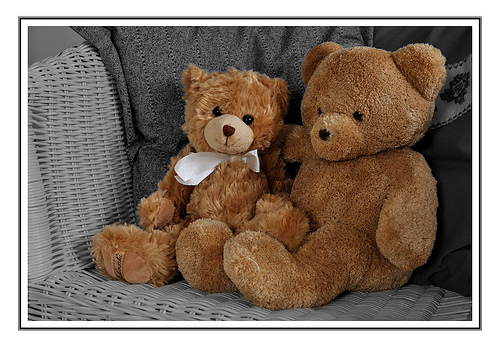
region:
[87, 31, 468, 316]
teddy bears in a chair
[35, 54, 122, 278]
wicker side of a chair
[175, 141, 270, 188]
white bow on a bear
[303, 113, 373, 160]
nose of a teddy bear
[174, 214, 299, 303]
front paws of a large bear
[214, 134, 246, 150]
mouth on a teddy bear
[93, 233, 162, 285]
front paws of a little bear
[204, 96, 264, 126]
eyes of a little teddy bear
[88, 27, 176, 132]
blanket on a chair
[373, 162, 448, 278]
arm of a teddy bear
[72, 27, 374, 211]
a grey blanket in a chair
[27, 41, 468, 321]
a white wicker chair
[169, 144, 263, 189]
a bow around a stuffed bear's neck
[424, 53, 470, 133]
white decorative trim on a blanket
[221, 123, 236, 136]
a brown nose on a stuffed bear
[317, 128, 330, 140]
a black nose on a stuffed bear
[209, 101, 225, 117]
a black eye on a stuffed bea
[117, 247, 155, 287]
a cloth pad on the bottom of a stuffed bear's paw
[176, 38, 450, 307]
a comfy stuffed bear in a wicker chair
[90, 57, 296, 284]
a shaggy stuffed bear in a wicker chair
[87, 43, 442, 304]
Two brown teddy bears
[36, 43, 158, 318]
Arm of wicker chair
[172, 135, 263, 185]
White bow on left teddy bear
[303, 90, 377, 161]
Right teddy bear's eyes and nose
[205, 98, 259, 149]
Right teddy bears nose and mouth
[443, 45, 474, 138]
Lace trim on pillow in background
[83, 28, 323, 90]
Grey pillow in background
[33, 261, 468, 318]
Seat of wicker chair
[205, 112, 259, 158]
White nose on teddy bear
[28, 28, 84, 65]
White wall behind wicker chair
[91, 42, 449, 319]
two brown teddy bears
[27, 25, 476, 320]
two brown teddy bears on a chair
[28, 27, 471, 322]
teddy bears on a wicker chair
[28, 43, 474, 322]
wicker chair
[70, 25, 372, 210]
gray blanket on a wicker chair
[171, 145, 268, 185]
a white bow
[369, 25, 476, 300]
gray pillow behind a teddy bear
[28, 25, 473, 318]
two brown teddy bears on a wicker chair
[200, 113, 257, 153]
tan and brown teddy bear nose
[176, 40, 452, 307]
plush teddy bear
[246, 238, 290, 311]
aprt of a leg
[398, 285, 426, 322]
aprt of a frame